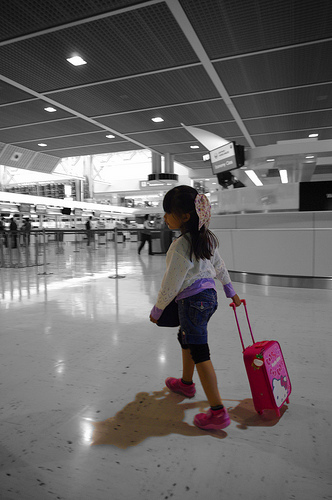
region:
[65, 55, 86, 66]
A bright light in the sky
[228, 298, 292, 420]
A pink carry on bag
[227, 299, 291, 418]
A pink luggage bag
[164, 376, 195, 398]
Pink shoe on right foot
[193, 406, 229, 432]
A pink shoe on a left foot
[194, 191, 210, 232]
A bow in a girl's hair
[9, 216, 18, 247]
person standing in an airport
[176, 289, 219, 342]
Blue jeans worn by girl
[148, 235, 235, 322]
Purple and white shirt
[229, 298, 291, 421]
A pink carry on luggage bag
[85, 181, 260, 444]
this is a girl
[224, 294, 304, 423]
this is a bag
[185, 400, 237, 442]
this is a shoe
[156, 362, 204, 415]
this is a shoe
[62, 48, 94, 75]
this is a ventilation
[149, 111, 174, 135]
this is a ventilation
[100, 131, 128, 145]
this is a ventilation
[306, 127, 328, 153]
this is a ventilation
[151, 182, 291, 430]
a girl carrying a suitcase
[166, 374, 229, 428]
girl wearing pink shoes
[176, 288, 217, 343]
girl wearing blue jeans shorts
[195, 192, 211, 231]
girl with a bow in her hair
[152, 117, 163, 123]
a white square light on the ceiling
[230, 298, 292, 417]
a pink suitcase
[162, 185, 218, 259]
girl with long brown hair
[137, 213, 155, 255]
a woman walking in an airport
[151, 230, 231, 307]
girl wearing a white sweater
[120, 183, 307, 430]
girl pulling a suitcase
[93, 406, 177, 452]
shadow of the girl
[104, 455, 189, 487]
the floor is tile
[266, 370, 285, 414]
hello kitty on the suitcase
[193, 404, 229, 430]
the shoe is pink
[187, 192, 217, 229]
bow in the hair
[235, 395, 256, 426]
shadow of the suitcase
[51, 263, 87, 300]
reflection on the floor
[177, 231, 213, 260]
hair of the girl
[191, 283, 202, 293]
the shirt is purple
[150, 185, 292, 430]
little girl carrying a pink bag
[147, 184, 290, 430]
little girl walking through the airport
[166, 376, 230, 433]
pink shoes on the girl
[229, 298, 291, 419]
pink bag held by the girl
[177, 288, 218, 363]
jean shorts on the girl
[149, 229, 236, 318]
purple and white coat on the girl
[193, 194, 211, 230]
white and pink bow in the girl's hair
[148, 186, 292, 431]
little girl walking to her airplane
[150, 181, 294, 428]
little girl wearing a white jacket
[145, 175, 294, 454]
Little girl pulling pink suitcase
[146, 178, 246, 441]
a little girl wearing pink shoes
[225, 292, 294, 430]
a hello kitty case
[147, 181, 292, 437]
a girl pulling a hello kitty case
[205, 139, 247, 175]
a large sign hanging on the wall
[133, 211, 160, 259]
a woman wearing a white shirt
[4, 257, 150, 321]
a light glare on the floor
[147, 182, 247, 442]
a little girl with long black hair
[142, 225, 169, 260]
a large trash can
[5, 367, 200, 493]
black spots on the floor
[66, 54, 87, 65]
building has a light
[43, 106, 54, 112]
building has a light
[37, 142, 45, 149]
building has a light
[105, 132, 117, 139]
building has a light